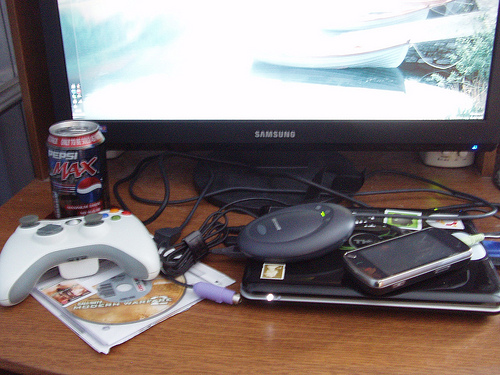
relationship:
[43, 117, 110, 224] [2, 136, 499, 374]
pepsi max on table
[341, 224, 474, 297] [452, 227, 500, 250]
cellphone has plug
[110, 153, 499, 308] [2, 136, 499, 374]
wires on table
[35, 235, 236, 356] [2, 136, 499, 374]
disks on table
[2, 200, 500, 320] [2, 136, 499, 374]
electronics on table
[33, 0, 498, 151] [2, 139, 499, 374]
monitor on desk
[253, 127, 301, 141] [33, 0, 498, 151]
samsung on monitor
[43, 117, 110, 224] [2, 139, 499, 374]
pepsi max on desk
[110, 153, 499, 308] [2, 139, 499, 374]
wires on desk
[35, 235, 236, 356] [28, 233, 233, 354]
disks in case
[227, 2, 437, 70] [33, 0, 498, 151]
boat on monitor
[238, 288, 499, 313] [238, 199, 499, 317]
edge of laptop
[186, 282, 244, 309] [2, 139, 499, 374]
purple cap on desk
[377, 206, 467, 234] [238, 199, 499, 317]
stickers on laptop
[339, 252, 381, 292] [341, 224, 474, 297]
edge of cellphone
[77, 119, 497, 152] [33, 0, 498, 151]
edge of monitor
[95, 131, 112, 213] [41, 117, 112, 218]
side of soda can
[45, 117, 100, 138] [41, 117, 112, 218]
top of soda can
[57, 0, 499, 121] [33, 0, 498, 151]
screen on monitor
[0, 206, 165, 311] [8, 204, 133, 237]
electronics with buttons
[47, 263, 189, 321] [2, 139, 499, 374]
disks on desk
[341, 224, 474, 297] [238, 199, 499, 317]
cellphone on laptop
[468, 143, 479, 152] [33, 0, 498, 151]
light on monitor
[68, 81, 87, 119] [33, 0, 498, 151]
icons on monitor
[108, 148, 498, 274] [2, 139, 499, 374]
cables on desk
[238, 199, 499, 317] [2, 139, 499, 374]
laptop on desk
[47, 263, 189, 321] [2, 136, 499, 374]
disks on table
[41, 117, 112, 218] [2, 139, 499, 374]
soda can on desk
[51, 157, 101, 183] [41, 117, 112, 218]
max on soda can